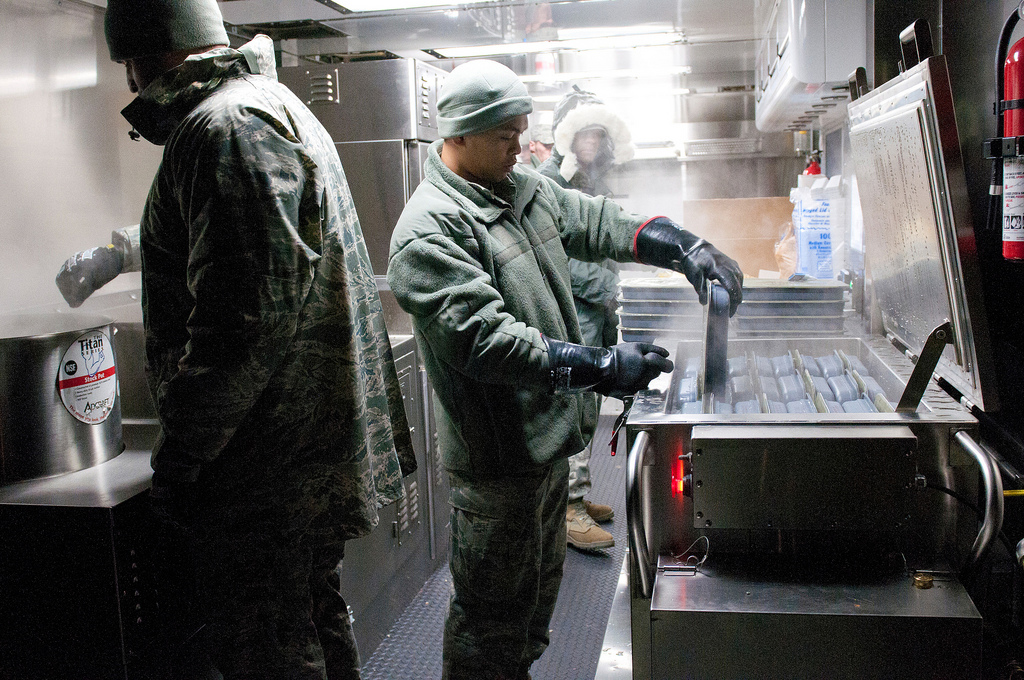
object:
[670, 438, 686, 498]
redglow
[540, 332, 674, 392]
glove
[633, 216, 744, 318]
glove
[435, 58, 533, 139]
beanie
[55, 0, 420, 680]
person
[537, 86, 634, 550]
person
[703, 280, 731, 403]
plate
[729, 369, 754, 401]
plate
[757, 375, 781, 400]
plate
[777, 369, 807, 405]
plate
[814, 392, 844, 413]
plate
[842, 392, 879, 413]
plate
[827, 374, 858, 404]
plate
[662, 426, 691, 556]
glow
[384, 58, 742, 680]
man